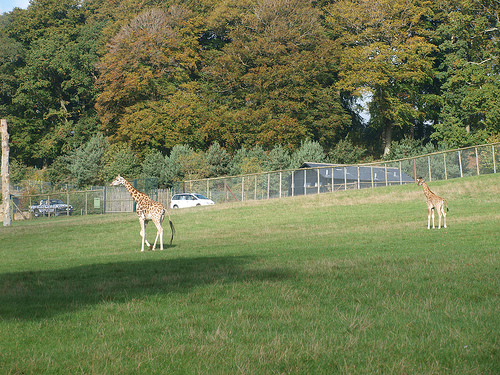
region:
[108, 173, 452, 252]
two giraffes are in a field.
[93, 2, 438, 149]
Some leaves are slightly yellow.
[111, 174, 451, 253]
the giraffe on the right is smaller.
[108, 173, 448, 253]
the giraffe on the left is larger.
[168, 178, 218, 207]
A car is in front of the fence.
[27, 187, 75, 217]
A truck is behind a fence.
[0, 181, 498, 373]
The grass is mostly green.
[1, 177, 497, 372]
thr grass has brown areas.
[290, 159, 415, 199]
a building is behind a fence.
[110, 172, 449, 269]
the giraffes are brownand white.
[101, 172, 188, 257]
giraffe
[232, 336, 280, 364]
short dark green grass in field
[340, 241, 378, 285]
short dark green grass in field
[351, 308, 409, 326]
short dark green grass in field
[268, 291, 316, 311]
short dark green grass in field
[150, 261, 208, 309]
short dark green grass in field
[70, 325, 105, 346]
short dark green grass in field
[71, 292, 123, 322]
short dark green grass in field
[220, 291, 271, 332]
short dark green grass in field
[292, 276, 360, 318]
short dark green grass in field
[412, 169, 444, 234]
giraffe in the grass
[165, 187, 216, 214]
white car on the road.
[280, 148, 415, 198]
building in the background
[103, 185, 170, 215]
wood fence gates on the fence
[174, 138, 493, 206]
chain link fence in the background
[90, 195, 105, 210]
sign on the fence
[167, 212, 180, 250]
black hair on the tail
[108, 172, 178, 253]
brown spots on the giraffe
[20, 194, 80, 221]
black and white truck in the background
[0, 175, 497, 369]
green grass covering the ground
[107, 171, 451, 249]
a couple of giraffes in a field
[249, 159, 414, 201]
a chain link metal fence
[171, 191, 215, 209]
a white car parked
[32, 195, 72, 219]
a gray truck parked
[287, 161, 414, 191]
a black building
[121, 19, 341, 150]
leafy trees on a hill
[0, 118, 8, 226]
a died tree stump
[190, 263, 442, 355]
a green grassy field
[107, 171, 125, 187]
a head of a giraffe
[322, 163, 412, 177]
a metal roof of a building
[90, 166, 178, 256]
giraffe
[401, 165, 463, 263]
baby giraffe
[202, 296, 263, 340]
short green and yellow grass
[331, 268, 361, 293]
short green and yellow grass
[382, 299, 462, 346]
short green and yellow grass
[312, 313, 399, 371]
short green and yellow grass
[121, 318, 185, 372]
short green and yellow grass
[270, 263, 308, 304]
short green and yellow grass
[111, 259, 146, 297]
short green and yellow grass